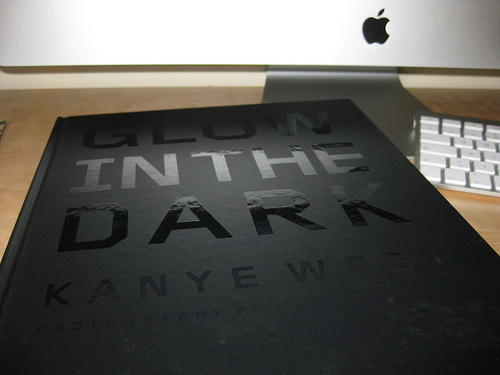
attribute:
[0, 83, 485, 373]
album — CD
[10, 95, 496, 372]
book — black, flat, album cover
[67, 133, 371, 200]
text — shiny, black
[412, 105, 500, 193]
keyboard — thin, white, silver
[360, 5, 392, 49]
logo — black, apple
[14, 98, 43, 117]
desk — beige, brown, wooden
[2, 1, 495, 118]
monitor stand — silver, computer